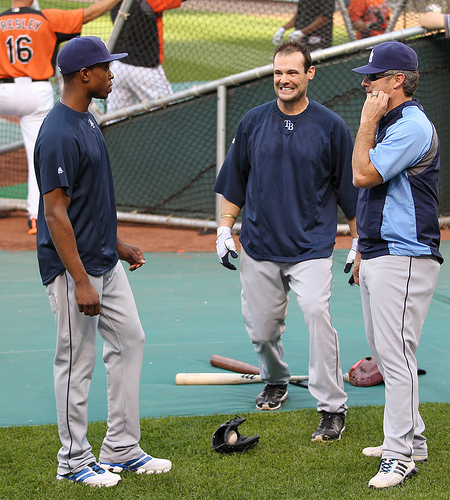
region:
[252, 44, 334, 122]
man smiling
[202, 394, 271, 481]
baseball glove and ball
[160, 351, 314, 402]
two baseball bats on the ground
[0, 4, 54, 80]
number sixteen orange jersey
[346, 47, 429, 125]
man wearing black sunglasses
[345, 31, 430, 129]
man wearing a wedding ring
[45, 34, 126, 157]
man wearing a blue cap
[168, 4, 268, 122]
mesh netting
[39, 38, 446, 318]
three men standing on grass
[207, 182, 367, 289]
man weating black and white gloves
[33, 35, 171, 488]
a black baseball player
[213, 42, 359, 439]
a white baseball player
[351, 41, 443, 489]
a white man in a baseball hat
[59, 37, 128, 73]
a black man's baseball cap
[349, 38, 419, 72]
a white man's baseball cap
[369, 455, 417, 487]
a white man's right foot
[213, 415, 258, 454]
a black baseball mitt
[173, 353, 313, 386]
two wooden baseball bats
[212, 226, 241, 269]
a man's right hand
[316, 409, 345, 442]
a man's black shoe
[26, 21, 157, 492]
Man in a blue cap, blue shirt and white pants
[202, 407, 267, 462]
Black baseball glove with a ball in it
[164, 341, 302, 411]
Two bats laying on the ground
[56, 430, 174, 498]
Blue and white shoes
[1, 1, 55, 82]
Orange shirt with number 16 on the back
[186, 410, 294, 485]
Black glove laying in the grass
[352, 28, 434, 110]
Man in a blue cap wearing sun glasses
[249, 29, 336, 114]
Man with a grin on his face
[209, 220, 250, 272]
Black and white glove on a man's hand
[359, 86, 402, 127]
Man's hand with a wedding ring on it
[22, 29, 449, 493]
three men on a baseball field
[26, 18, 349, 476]
two men wearing blue shirt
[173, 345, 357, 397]
two baseball bats on the floor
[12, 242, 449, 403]
floor is artificial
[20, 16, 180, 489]
man stand in green grass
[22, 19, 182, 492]
man wears white shoes with blue stripes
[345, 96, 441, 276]
a blue shirt with stripes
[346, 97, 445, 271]
blue shirt with light blue tripes on side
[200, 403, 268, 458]
black baseball glove with white ball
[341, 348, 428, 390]
brown glove on the floor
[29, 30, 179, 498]
a standing baseball player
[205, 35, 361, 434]
a standing baseball player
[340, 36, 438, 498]
a standing baseball player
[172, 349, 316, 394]
two bats laying on the ground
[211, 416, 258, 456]
a black leather mitt and baseball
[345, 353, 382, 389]
a brown leather mitt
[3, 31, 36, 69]
player number 16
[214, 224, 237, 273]
white and black baseball glove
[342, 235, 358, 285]
white and black baseball glove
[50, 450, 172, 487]
blue and white tennis shoes